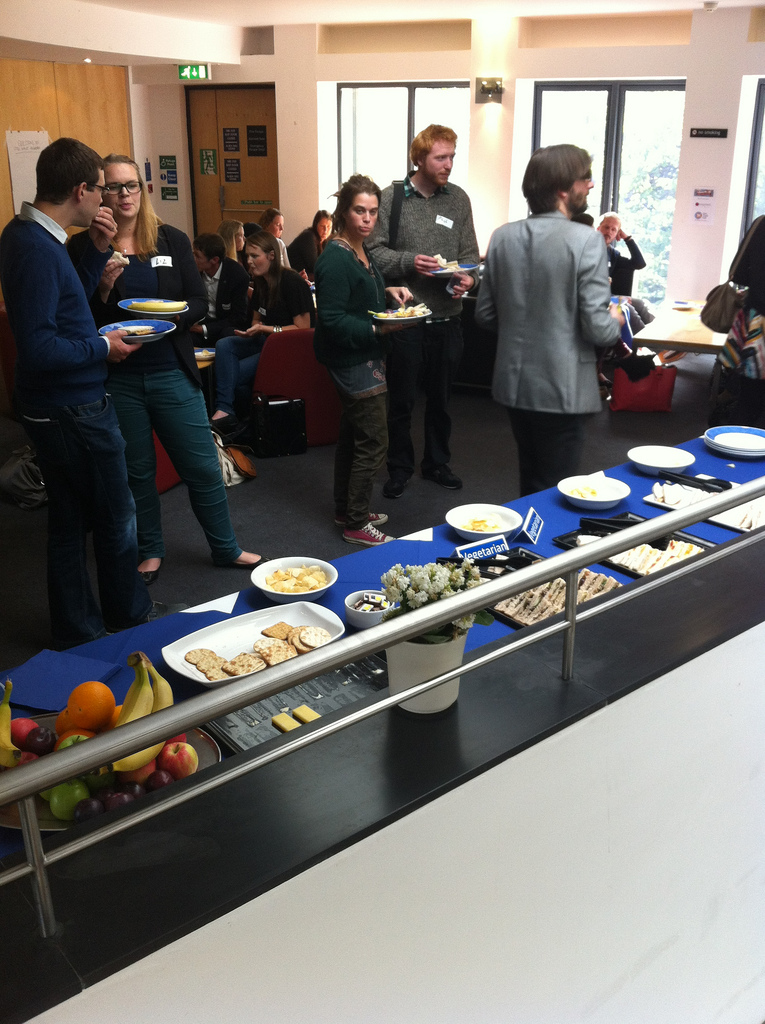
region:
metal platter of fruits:
[0, 649, 224, 835]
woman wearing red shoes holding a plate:
[310, 170, 433, 547]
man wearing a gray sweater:
[363, 120, 482, 495]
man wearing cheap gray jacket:
[472, 141, 634, 496]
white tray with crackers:
[157, 598, 346, 691]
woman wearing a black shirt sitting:
[206, 231, 315, 445]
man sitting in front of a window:
[592, 211, 645, 295]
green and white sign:
[173, 57, 211, 81]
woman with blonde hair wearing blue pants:
[59, 152, 269, 583]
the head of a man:
[393, 123, 473, 199]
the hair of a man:
[410, 117, 460, 151]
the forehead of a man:
[432, 143, 456, 151]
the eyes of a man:
[432, 150, 458, 169]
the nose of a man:
[432, 154, 471, 173]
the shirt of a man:
[365, 182, 485, 317]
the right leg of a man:
[367, 303, 436, 480]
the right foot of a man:
[382, 462, 421, 512]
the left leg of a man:
[426, 300, 469, 490]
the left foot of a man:
[424, 456, 467, 493]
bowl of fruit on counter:
[0, 648, 234, 850]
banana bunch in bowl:
[101, 647, 187, 777]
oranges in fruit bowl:
[50, 677, 134, 742]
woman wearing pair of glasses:
[104, 170, 140, 202]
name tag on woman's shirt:
[144, 244, 172, 270]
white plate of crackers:
[157, 587, 352, 684]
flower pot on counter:
[368, 548, 496, 728]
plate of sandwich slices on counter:
[485, 547, 630, 639]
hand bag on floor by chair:
[246, 386, 311, 460]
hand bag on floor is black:
[247, 380, 319, 460]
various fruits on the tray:
[6, 643, 200, 821]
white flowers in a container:
[383, 558, 464, 714]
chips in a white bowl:
[249, 550, 342, 598]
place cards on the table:
[454, 534, 511, 561]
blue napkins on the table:
[2, 643, 121, 688]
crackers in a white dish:
[156, 596, 353, 682]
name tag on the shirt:
[431, 203, 456, 232]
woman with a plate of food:
[301, 170, 394, 548]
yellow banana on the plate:
[114, 288, 190, 315]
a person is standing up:
[479, 136, 648, 497]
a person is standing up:
[316, 177, 430, 558]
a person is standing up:
[375, 114, 483, 508]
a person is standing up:
[4, 140, 162, 652]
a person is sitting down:
[211, 226, 310, 420]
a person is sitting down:
[591, 193, 648, 297]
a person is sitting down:
[187, 224, 241, 334]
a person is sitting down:
[261, 208, 292, 264]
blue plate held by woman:
[112, 288, 191, 326]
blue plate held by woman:
[354, 278, 445, 347]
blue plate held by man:
[600, 294, 677, 340]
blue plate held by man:
[73, 311, 210, 349]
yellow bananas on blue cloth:
[110, 633, 177, 757]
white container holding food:
[165, 595, 327, 672]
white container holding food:
[251, 546, 344, 605]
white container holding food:
[428, 492, 525, 547]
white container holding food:
[550, 469, 628, 509]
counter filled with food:
[0, 418, 762, 893]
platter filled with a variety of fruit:
[0, 650, 226, 818]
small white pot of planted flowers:
[376, 555, 485, 715]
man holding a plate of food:
[2, 138, 183, 611]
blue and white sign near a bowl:
[441, 496, 545, 549]